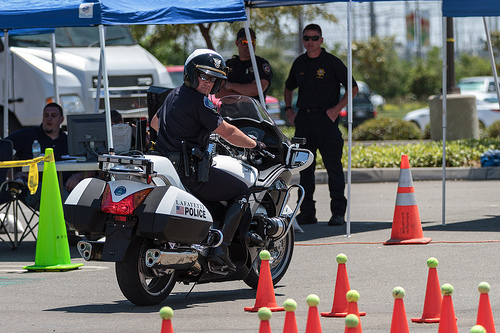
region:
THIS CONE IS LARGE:
[16, 143, 88, 279]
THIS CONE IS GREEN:
[23, 140, 79, 282]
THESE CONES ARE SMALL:
[141, 243, 498, 331]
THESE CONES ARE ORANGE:
[142, 241, 499, 331]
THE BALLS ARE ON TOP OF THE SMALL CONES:
[150, 237, 499, 332]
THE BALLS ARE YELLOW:
[153, 243, 498, 331]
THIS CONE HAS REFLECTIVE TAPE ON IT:
[376, 140, 433, 255]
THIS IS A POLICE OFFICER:
[146, 47, 256, 282]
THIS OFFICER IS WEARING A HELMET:
[176, 47, 235, 100]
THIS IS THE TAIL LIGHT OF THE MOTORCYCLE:
[98, 173, 173, 244]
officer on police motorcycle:
[150, 48, 265, 278]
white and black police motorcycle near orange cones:
[62, 90, 312, 305]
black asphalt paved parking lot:
[0, 176, 496, 326]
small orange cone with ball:
[320, 261, 365, 316]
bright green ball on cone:
[335, 250, 345, 261]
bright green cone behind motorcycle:
[20, 145, 81, 270]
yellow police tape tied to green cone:
[0, 150, 55, 195]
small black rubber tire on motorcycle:
[111, 225, 176, 305]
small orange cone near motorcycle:
[240, 256, 280, 307]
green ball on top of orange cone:
[257, 246, 270, 261]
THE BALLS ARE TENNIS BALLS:
[140, 237, 496, 328]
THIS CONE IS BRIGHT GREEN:
[25, 138, 83, 293]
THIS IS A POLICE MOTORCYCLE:
[87, 125, 332, 307]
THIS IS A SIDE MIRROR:
[275, 150, 315, 183]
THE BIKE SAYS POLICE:
[166, 191, 222, 236]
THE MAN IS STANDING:
[276, 23, 363, 229]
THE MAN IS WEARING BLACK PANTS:
[285, 100, 365, 215]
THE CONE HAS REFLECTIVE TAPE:
[381, 165, 422, 215]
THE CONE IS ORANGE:
[245, 245, 295, 320]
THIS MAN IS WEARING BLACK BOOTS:
[208, 193, 253, 283]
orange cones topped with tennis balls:
[154, 248, 497, 331]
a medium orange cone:
[383, 151, 428, 245]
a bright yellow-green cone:
[29, 145, 76, 272]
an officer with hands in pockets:
[289, 18, 361, 230]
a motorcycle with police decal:
[72, 90, 313, 305]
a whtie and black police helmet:
[182, 48, 228, 93]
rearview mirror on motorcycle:
[285, 139, 313, 174]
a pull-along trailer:
[4, 46, 169, 131]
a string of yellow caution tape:
[0, 153, 54, 193]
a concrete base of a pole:
[429, 95, 479, 145]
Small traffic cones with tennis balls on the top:
[158, 250, 495, 332]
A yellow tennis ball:
[285, 300, 295, 309]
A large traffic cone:
[385, 157, 431, 245]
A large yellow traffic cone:
[29, 151, 83, 269]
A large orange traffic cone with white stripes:
[384, 154, 427, 243]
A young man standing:
[285, 25, 357, 222]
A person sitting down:
[14, 104, 66, 155]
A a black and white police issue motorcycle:
[61, 49, 313, 301]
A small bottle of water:
[30, 137, 41, 156]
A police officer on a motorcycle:
[151, 49, 263, 269]